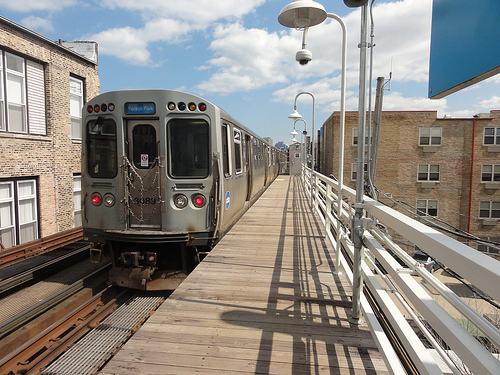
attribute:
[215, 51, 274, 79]
clouds — white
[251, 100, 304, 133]
sky — blue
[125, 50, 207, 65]
clouds — white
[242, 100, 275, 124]
sky — blue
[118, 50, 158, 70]
clouds — white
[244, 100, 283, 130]
sky — blue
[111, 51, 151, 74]
clouds — white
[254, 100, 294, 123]
sky — blue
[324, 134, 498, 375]
railing — white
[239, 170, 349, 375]
platform — wooden